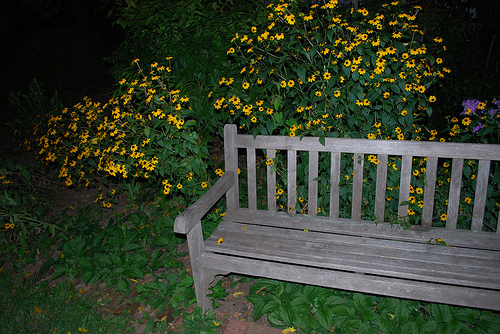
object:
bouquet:
[20, 0, 500, 223]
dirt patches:
[0, 192, 253, 334]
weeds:
[0, 168, 500, 334]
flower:
[21, 0, 499, 221]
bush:
[18, 0, 500, 221]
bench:
[173, 124, 500, 318]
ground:
[0, 149, 500, 334]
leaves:
[6, 195, 188, 314]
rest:
[174, 171, 236, 251]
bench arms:
[173, 170, 234, 234]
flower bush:
[21, 0, 500, 224]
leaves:
[247, 277, 500, 334]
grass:
[0, 204, 500, 334]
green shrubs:
[0, 0, 500, 334]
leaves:
[145, 117, 204, 175]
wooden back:
[222, 124, 500, 233]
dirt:
[213, 291, 279, 334]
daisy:
[24, 0, 500, 227]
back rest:
[223, 124, 500, 234]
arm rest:
[174, 170, 235, 233]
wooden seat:
[173, 124, 500, 315]